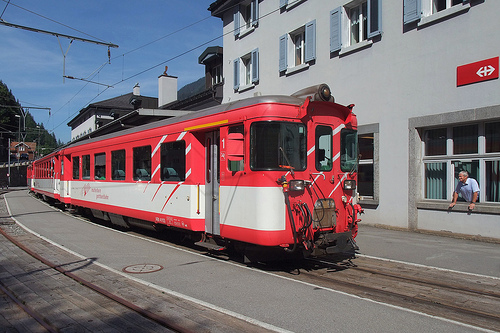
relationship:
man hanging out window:
[448, 169, 481, 215] [443, 154, 484, 201]